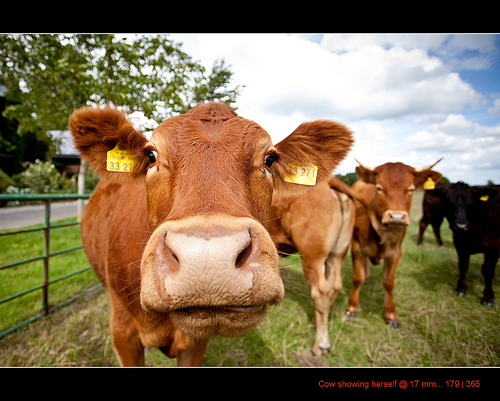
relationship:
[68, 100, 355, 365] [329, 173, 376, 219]
cow has a tail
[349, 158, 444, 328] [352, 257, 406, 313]
cow has front legs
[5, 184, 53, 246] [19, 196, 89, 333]
street next to fence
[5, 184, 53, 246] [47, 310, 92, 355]
street next to grass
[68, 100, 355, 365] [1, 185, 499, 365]
cow on grass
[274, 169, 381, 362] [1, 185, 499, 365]
cow on grass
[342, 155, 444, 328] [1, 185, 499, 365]
cow on grass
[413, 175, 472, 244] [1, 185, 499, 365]
cow on grass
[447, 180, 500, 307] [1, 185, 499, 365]
black cow on grass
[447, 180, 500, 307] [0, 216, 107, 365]
black cow on grass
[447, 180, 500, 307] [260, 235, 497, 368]
black cow on grass